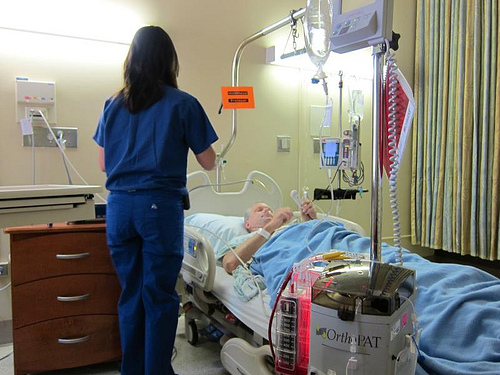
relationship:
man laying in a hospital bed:
[221, 201, 500, 375] [171, 207, 311, 319]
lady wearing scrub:
[92, 24, 218, 375] [96, 82, 216, 366]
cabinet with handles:
[1, 219, 116, 373] [52, 247, 94, 349]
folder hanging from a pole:
[379, 60, 416, 181] [368, 49, 383, 264]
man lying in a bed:
[221, 201, 500, 375] [203, 234, 312, 300]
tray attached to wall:
[0, 184, 105, 212] [5, 2, 122, 72]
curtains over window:
[407, 0, 499, 262] [407, 0, 499, 280]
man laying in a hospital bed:
[221, 201, 500, 375] [168, 163, 497, 360]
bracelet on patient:
[252, 225, 277, 243] [220, 198, 499, 357]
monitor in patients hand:
[288, 188, 309, 207] [297, 200, 317, 222]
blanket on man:
[240, 218, 499, 373] [221, 201, 500, 375]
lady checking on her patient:
[92, 24, 218, 375] [216, 184, 341, 269]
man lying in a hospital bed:
[227, 201, 388, 288] [178, 186, 490, 373]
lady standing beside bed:
[92, 24, 218, 375] [175, 163, 496, 358]